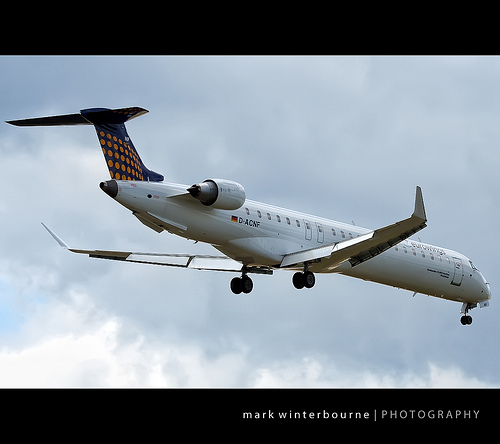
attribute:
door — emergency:
[449, 251, 467, 289]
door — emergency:
[313, 215, 326, 248]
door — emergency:
[301, 212, 313, 243]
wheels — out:
[229, 274, 254, 297]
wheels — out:
[291, 269, 316, 290]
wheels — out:
[458, 312, 475, 327]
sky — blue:
[1, 55, 499, 389]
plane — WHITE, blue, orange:
[9, 106, 490, 335]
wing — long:
[279, 183, 427, 268]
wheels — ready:
[286, 263, 318, 288]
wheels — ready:
[227, 273, 254, 297]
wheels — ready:
[459, 315, 473, 326]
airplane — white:
[38, 130, 468, 307]